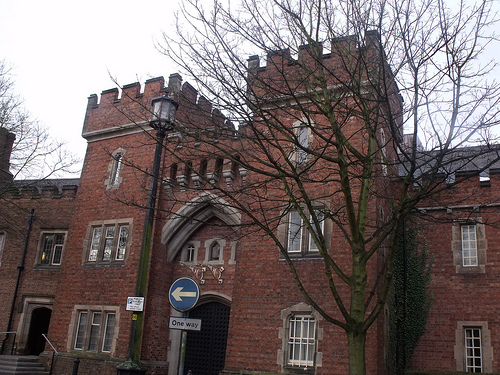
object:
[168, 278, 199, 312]
aarow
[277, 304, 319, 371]
window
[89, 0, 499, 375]
tree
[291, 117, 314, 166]
window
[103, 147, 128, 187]
window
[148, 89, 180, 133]
light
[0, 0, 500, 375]
urban setting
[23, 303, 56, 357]
door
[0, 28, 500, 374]
building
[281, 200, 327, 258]
window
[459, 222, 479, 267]
window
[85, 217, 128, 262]
window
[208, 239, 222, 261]
window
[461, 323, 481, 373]
window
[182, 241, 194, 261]
window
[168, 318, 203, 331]
one way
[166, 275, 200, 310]
sign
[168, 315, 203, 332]
sign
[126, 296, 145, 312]
sign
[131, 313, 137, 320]
sign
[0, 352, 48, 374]
stairs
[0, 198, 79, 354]
brick wall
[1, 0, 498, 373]
armory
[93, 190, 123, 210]
brick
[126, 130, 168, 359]
lamp post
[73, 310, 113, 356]
window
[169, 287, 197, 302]
arrow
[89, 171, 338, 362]
building